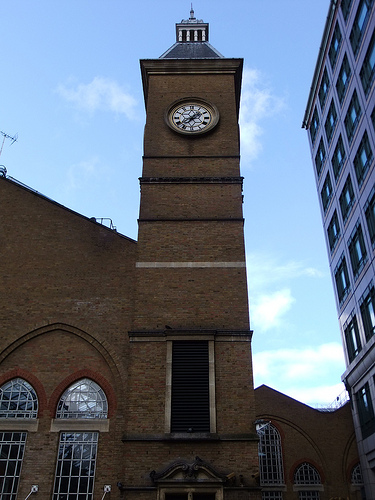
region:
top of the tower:
[162, 12, 213, 41]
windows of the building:
[5, 366, 113, 494]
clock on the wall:
[133, 82, 208, 147]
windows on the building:
[302, 73, 360, 302]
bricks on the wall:
[123, 262, 231, 316]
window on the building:
[242, 416, 320, 480]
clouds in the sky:
[245, 269, 335, 380]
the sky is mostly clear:
[51, 76, 115, 192]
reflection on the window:
[53, 360, 108, 425]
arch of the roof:
[8, 161, 141, 246]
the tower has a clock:
[172, 100, 218, 134]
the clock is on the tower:
[169, 98, 214, 134]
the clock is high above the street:
[171, 102, 212, 132]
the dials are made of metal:
[179, 110, 203, 129]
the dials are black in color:
[180, 110, 202, 126]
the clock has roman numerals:
[174, 103, 212, 133]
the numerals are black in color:
[173, 100, 209, 131]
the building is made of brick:
[1, 52, 257, 496]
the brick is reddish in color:
[1, 70, 259, 498]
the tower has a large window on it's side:
[169, 333, 223, 432]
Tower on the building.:
[114, 0, 264, 497]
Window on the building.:
[43, 362, 115, 498]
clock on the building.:
[163, 93, 220, 136]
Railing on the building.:
[306, 387, 350, 414]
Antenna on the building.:
[1, 120, 20, 159]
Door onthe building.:
[147, 454, 228, 499]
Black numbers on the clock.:
[164, 93, 221, 134]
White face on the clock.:
[166, 97, 219, 133]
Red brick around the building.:
[43, 362, 118, 421]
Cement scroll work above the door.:
[145, 455, 232, 489]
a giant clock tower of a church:
[133, 22, 273, 451]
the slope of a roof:
[162, 11, 222, 58]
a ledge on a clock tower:
[129, 161, 245, 196]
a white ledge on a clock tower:
[139, 251, 248, 281]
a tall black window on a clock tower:
[158, 328, 218, 443]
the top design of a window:
[148, 461, 218, 488]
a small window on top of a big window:
[56, 378, 111, 431]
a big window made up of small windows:
[48, 426, 95, 498]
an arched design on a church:
[253, 412, 331, 491]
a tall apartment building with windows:
[285, 70, 367, 267]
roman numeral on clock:
[194, 104, 202, 111]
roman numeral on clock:
[201, 110, 208, 117]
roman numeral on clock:
[202, 114, 210, 120]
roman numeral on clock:
[200, 120, 206, 126]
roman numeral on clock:
[196, 125, 201, 130]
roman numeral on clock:
[188, 126, 195, 131]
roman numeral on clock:
[180, 124, 186, 130]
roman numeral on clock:
[175, 120, 180, 125]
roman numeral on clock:
[172, 114, 177, 119]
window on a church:
[52, 428, 97, 499]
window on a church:
[49, 384, 107, 417]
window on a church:
[1, 428, 29, 496]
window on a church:
[255, 423, 281, 484]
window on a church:
[288, 464, 323, 496]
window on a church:
[351, 468, 364, 497]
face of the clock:
[148, 78, 239, 162]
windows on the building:
[4, 371, 127, 430]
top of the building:
[239, 368, 319, 425]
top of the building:
[125, 5, 264, 84]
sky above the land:
[250, 222, 324, 347]